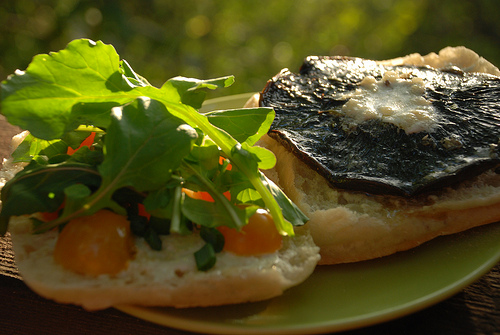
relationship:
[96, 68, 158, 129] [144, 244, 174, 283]
greens are on bread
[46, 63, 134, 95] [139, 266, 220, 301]
lettuce on sandwich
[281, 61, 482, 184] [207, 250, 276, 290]
mushroom on sandwich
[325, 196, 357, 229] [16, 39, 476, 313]
bread for sandwich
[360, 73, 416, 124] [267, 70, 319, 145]
base on mushroom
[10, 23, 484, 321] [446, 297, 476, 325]
plate on table